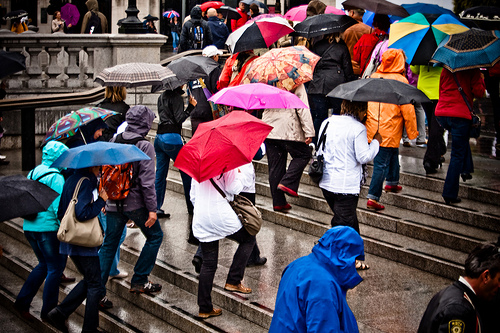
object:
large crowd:
[0, 0, 498, 332]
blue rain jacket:
[22, 140, 70, 233]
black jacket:
[423, 279, 486, 333]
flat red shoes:
[271, 184, 300, 211]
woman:
[316, 98, 383, 270]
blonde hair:
[104, 83, 126, 103]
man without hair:
[203, 7, 229, 48]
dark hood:
[190, 8, 202, 19]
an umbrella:
[199, 1, 224, 12]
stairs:
[0, 108, 499, 333]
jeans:
[366, 146, 401, 202]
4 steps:
[145, 130, 498, 283]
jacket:
[318, 114, 381, 195]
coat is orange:
[365, 49, 419, 148]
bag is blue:
[188, 23, 205, 49]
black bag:
[307, 122, 328, 183]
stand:
[0, 32, 168, 151]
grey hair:
[465, 245, 500, 280]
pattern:
[186, 160, 256, 243]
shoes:
[384, 185, 403, 194]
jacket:
[268, 225, 368, 333]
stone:
[239, 300, 275, 329]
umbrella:
[172, 110, 274, 185]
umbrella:
[207, 83, 308, 110]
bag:
[98, 163, 134, 200]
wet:
[214, 216, 321, 311]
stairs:
[0, 216, 274, 333]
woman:
[365, 48, 423, 210]